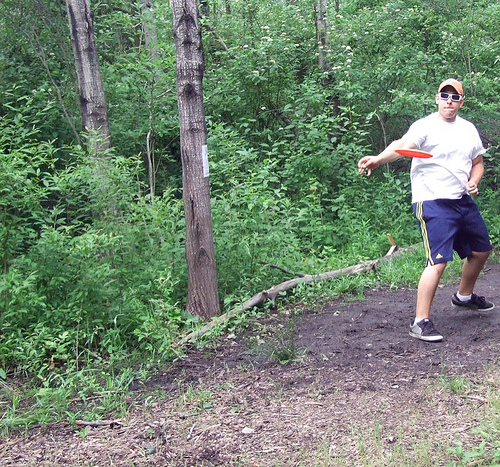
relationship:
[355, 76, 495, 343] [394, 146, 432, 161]
man tossing frisbee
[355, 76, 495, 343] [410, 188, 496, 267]
man wearing shorts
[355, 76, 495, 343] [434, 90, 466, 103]
man wearing sunglasses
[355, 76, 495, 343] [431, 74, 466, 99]
man wearing hat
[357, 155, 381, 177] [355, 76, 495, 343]
hand of man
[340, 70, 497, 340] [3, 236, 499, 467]
man on ground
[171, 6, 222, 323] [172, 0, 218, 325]
trunk of tree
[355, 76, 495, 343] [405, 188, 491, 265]
man wears shorts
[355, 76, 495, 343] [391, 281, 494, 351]
man wears sneakers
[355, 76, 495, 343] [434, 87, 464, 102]
man wears sunglasses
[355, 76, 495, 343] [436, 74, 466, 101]
man wears hat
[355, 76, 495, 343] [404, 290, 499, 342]
man has sneakers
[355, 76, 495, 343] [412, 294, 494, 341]
man has feet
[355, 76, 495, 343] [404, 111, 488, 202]
man wears shirt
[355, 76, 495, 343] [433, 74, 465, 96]
man wears cap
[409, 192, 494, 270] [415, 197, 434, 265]
shorts have stripes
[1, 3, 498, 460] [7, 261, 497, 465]
foliage next to path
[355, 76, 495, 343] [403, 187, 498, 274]
man wears shorts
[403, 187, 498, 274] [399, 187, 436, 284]
shorts have stripes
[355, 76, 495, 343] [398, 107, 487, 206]
man wears shirt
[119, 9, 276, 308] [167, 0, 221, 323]
tree has trunk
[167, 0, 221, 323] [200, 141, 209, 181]
trunk has sign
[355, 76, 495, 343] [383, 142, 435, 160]
man playing frisbee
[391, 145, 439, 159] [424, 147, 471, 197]
frisbee thrown ground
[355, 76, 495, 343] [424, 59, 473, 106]
man wearing hat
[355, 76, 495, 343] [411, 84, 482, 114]
man wearing sunglasses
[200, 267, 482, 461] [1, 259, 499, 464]
ground covered in dirt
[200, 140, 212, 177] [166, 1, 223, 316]
sign on tree